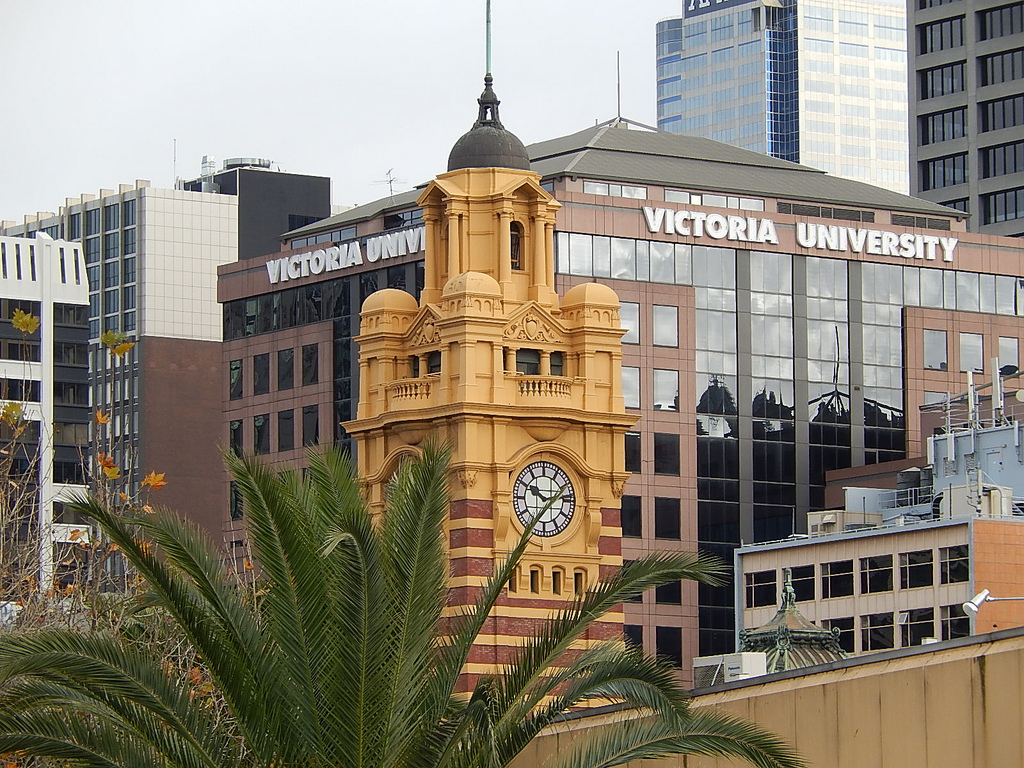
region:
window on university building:
[652, 301, 681, 344]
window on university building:
[652, 366, 679, 411]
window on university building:
[652, 497, 681, 542]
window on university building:
[652, 579, 679, 606]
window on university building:
[652, 625, 681, 670]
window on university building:
[619, 299, 644, 344]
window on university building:
[623, 431, 639, 474]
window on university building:
[621, 495, 639, 534]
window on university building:
[627, 558, 641, 601]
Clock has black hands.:
[531, 474, 569, 523]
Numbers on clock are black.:
[503, 465, 592, 548]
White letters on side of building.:
[640, 190, 967, 267]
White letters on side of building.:
[271, 225, 452, 274]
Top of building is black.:
[451, 79, 531, 172]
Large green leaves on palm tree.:
[57, 500, 696, 758]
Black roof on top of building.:
[525, 126, 934, 221]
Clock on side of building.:
[385, 186, 626, 733]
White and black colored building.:
[8, 240, 88, 608]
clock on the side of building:
[503, 452, 584, 536]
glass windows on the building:
[751, 253, 796, 408]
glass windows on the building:
[555, 234, 695, 280]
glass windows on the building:
[326, 281, 353, 352]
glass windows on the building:
[205, 344, 323, 386]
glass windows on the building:
[678, 7, 711, 53]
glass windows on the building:
[50, 323, 88, 362]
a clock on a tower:
[507, 446, 588, 555]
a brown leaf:
[133, 460, 176, 499]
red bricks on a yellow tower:
[432, 487, 641, 721]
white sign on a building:
[627, 196, 964, 276]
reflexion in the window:
[615, 310, 911, 647]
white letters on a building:
[259, 216, 437, 292]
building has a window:
[689, 242, 737, 288]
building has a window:
[749, 254, 792, 300]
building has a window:
[744, 290, 792, 319]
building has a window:
[752, 308, 791, 359]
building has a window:
[698, 373, 737, 424]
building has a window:
[752, 371, 795, 425]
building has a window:
[803, 376, 849, 435]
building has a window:
[866, 384, 902, 432]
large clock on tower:
[510, 451, 580, 543]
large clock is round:
[509, 461, 587, 539]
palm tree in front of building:
[3, 435, 833, 767]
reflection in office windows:
[652, 321, 922, 593]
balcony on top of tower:
[504, 362, 578, 410]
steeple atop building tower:
[439, 9, 537, 178]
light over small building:
[958, 578, 994, 621]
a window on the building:
[752, 256, 794, 291]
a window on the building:
[759, 383, 811, 444]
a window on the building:
[773, 454, 816, 532]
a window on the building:
[724, 489, 816, 566]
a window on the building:
[682, 427, 721, 484]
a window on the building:
[663, 483, 684, 518]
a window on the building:
[667, 448, 694, 484]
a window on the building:
[638, 312, 677, 339]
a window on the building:
[588, 246, 666, 273]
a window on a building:
[558, 228, 594, 280]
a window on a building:
[653, 431, 677, 476]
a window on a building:
[589, 232, 603, 267]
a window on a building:
[702, 494, 741, 545]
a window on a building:
[607, 236, 631, 275]